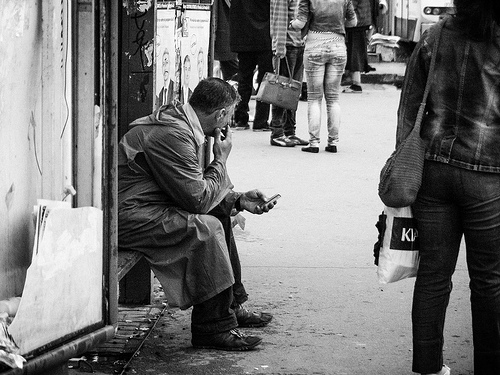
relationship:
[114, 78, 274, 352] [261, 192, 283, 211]
man holding cell phone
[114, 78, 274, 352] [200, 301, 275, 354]
man has shoes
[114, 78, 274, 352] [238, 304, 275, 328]
man has shoe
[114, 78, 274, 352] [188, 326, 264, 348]
man has shoe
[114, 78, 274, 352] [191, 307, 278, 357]
man has shoes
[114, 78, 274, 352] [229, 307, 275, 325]
man has shoe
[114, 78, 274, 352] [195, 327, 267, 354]
man has shoe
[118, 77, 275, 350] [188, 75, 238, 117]
man has hair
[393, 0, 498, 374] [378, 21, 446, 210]
girl carrying purse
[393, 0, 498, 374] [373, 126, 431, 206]
girl carrying a bag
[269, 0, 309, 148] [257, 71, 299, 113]
man carrying a bag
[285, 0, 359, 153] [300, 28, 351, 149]
people wearing jeans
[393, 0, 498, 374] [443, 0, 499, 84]
girl has hair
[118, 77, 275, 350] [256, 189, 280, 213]
man holds a phone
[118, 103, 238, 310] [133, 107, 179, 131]
coat has hood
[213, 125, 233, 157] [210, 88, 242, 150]
hand touches h face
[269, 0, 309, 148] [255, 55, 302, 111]
man holds a bag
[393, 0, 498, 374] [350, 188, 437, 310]
girl carries a shopping bag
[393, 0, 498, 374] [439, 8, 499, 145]
girl has hair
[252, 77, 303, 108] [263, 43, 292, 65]
bag in woman's hand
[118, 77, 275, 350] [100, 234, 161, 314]
man sitting on a stoop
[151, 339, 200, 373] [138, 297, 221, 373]
shadow on ground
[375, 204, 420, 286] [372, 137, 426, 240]
bag in woman's hand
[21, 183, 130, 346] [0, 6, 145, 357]
broken area of a truck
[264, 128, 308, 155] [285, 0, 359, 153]
sneakers on a people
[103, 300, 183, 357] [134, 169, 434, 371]
floor in a street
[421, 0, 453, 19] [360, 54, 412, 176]
sign above a road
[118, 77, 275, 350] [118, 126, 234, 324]
man sitting with coat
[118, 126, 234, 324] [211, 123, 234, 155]
coat on and hand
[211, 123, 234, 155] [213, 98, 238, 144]
hand to h face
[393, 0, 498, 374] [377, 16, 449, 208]
girl walking with bag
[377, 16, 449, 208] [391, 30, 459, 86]
bag on shoulder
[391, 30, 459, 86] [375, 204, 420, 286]
shoulder and bag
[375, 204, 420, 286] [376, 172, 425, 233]
bag in her hand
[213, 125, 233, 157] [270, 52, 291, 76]
hand clutching handle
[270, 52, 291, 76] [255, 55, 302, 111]
handle of a bag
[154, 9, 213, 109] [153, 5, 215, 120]
poster on a wall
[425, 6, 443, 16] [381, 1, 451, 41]
lights on vehicle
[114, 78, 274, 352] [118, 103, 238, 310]
man wearing a coat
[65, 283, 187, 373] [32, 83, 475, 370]
cigarette butts littering ground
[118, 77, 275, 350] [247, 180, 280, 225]
man holding phone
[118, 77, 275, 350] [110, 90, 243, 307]
man wearing coat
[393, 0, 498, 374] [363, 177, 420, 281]
girl holding bag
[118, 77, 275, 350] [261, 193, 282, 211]
man holding cell phone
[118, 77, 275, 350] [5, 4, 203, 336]
man sitting truck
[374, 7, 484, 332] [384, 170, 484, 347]
girl wearing jeans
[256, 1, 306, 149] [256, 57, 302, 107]
man holding bag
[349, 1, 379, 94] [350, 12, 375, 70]
woman wearing skirt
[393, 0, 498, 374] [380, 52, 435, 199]
girl with bag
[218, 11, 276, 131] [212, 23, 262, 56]
man wearing clothes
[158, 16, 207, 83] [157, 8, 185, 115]
poster on door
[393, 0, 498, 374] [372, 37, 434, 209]
girl carrying bag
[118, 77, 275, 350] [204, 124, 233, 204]
man sitting hand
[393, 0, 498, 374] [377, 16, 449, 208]
girl carrying bag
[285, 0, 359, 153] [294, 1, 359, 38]
people wearing top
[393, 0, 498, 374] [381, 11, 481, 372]
girl wearing jeans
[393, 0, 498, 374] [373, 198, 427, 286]
girl carrying bag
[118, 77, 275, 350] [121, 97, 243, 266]
man wearing coat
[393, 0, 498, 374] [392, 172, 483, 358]
girl wearing pants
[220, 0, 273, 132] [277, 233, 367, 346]
man on sidewalk